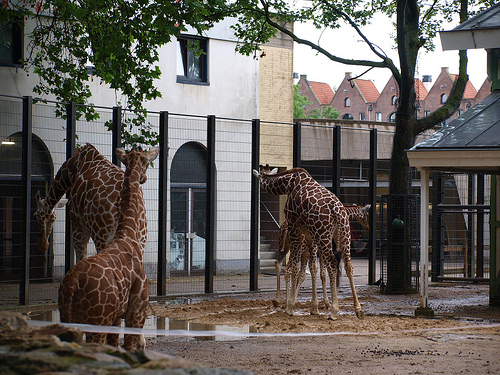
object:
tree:
[229, 0, 500, 296]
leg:
[332, 227, 363, 312]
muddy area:
[147, 293, 500, 338]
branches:
[256, 0, 388, 71]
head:
[114, 145, 162, 185]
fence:
[0, 92, 490, 306]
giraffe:
[57, 146, 161, 355]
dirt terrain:
[0, 279, 499, 374]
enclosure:
[2, 91, 499, 375]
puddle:
[18, 308, 262, 336]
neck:
[109, 181, 148, 256]